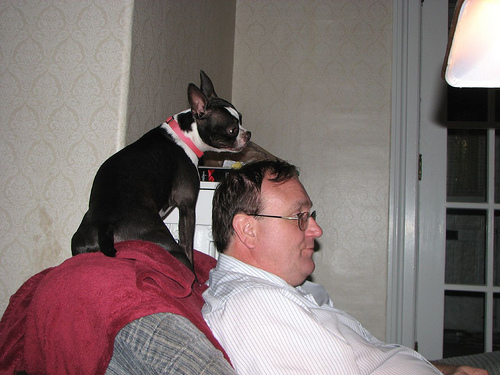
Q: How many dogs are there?
A: 1.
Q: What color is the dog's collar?
A: Pink.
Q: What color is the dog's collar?
A: Red.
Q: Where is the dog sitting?
A: On the back of the chair.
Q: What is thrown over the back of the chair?
A: Red blanket.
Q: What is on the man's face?
A: Eyeglasses.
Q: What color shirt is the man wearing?
A: White.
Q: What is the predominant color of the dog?
A: Black.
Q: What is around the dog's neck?
A: A collar.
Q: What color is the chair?
A: Gray.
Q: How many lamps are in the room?
A: 1.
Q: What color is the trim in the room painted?
A: White.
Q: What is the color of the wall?
A: White.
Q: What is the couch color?
A: Grey.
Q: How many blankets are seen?
A: 1.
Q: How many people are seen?
A: 1.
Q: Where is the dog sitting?
A: In the back of the chair.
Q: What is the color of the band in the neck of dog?
A: Pink.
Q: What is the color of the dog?
A: Black and white.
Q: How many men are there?
A: One.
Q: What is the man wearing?
A: Glasses.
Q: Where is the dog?
A: On back of chair.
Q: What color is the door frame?
A: White.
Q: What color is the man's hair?
A: Brown.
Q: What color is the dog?
A: Black and white.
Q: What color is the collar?
A: Pink.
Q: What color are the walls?
A: White.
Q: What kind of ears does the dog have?
A: Pointy.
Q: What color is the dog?
A: Black and white.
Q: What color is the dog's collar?
A: Pink.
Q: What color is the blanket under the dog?
A: Red.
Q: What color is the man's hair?
A: Brown.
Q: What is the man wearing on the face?
A: Glasses.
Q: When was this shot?
A: Nighttime.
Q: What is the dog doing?
A: Sitting on chair.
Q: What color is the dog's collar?
A: Red.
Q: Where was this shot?
A: Living room.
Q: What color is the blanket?
A: Red.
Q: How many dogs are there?
A: 1.